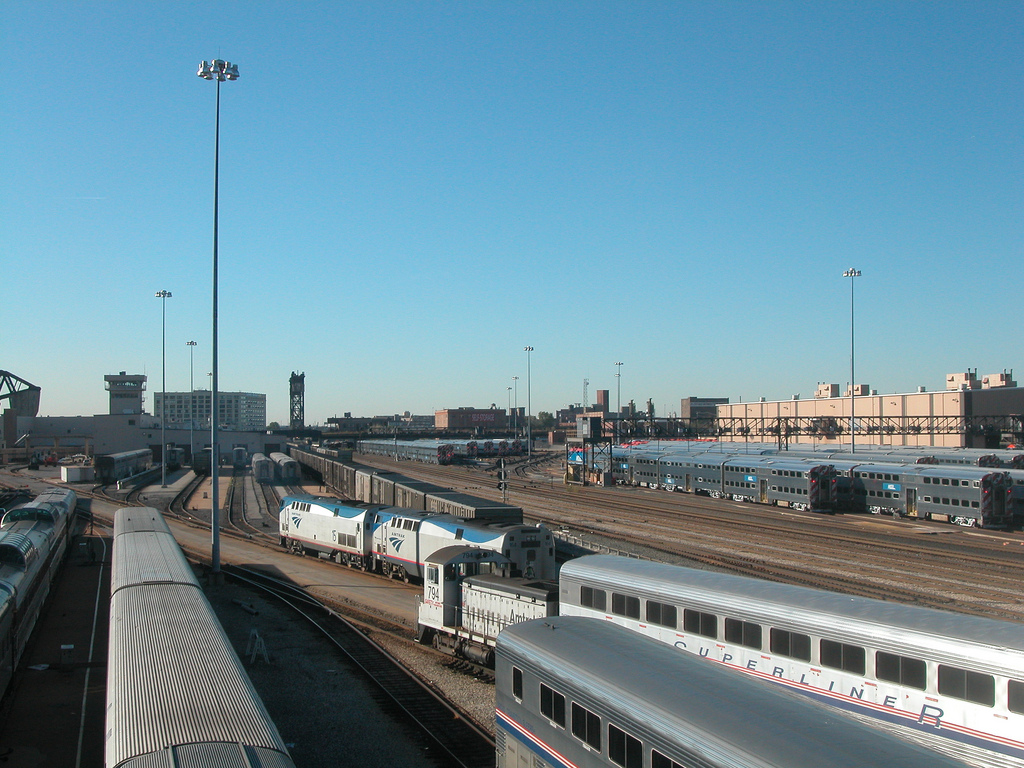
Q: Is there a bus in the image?
A: No, there are no buses.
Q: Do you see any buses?
A: No, there are no buses.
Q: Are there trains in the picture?
A: Yes, there is a train.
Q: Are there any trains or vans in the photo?
A: Yes, there is a train.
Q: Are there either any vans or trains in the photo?
A: Yes, there is a train.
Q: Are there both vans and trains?
A: No, there is a train but no vans.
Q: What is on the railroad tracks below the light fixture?
A: The train is on the tracks.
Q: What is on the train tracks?
A: The train is on the tracks.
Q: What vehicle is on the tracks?
A: The vehicle is a train.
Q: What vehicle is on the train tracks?
A: The vehicle is a train.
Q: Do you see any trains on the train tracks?
A: Yes, there is a train on the train tracks.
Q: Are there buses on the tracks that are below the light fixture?
A: No, there is a train on the tracks.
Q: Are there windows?
A: Yes, there is a window.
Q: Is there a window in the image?
A: Yes, there is a window.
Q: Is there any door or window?
A: Yes, there is a window.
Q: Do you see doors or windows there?
A: Yes, there is a window.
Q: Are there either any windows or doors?
A: Yes, there is a window.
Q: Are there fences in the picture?
A: No, there are no fences.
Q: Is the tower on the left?
A: Yes, the tower is on the left of the image.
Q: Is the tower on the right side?
A: No, the tower is on the left of the image.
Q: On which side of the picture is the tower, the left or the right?
A: The tower is on the left of the image.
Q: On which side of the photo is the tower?
A: The tower is on the left of the image.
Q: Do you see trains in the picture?
A: Yes, there is a train.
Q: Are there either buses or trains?
A: Yes, there is a train.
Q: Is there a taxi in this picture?
A: No, there are no taxis.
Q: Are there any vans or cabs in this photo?
A: No, there are no cabs or vans.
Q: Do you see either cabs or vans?
A: No, there are no cabs or vans.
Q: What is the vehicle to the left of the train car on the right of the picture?
A: The vehicle is a train.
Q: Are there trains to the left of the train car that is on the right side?
A: Yes, there is a train to the left of the train car.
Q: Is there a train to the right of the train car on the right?
A: No, the train is to the left of the train car.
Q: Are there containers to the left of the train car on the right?
A: No, there is a train to the left of the train car.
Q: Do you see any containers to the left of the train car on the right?
A: No, there is a train to the left of the train car.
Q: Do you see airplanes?
A: No, there are no airplanes.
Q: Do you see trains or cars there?
A: Yes, there is a train.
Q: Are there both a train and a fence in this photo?
A: No, there is a train but no fences.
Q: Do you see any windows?
A: Yes, there is a window.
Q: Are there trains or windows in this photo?
A: Yes, there is a window.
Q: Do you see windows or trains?
A: Yes, there is a window.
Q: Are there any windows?
A: Yes, there is a window.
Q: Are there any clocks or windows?
A: Yes, there is a window.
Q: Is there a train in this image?
A: Yes, there is a train.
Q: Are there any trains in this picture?
A: Yes, there is a train.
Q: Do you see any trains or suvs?
A: Yes, there is a train.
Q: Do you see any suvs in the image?
A: No, there are no suvs.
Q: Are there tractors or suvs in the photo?
A: No, there are no suvs or tractors.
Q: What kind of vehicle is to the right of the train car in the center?
A: The vehicle is a train.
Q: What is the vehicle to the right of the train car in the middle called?
A: The vehicle is a train.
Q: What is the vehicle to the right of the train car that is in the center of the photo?
A: The vehicle is a train.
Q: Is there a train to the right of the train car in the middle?
A: Yes, there is a train to the right of the train car.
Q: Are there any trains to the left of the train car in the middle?
A: No, the train is to the right of the train car.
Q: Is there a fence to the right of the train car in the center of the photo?
A: No, there is a train to the right of the train car.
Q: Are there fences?
A: No, there are no fences.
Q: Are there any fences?
A: No, there are no fences.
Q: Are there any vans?
A: No, there are no vans.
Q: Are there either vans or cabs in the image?
A: No, there are no vans or cabs.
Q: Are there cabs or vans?
A: No, there are no vans or cabs.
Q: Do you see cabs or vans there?
A: No, there are no vans or cabs.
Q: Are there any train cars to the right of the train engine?
A: No, the train car is to the left of the train engine.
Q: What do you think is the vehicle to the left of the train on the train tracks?
A: The vehicle is a train car.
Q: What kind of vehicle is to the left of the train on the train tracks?
A: The vehicle is a train car.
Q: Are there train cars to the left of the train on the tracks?
A: Yes, there is a train car to the left of the train.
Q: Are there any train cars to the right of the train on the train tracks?
A: No, the train car is to the left of the train.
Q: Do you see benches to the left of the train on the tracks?
A: No, there is a train car to the left of the train.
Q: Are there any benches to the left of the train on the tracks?
A: No, there is a train car to the left of the train.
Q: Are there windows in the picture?
A: Yes, there is a window.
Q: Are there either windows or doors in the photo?
A: Yes, there is a window.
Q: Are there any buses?
A: No, there are no buses.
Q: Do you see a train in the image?
A: Yes, there is a train.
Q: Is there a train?
A: Yes, there is a train.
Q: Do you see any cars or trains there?
A: Yes, there is a train.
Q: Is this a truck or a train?
A: This is a train.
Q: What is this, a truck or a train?
A: This is a train.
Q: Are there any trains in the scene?
A: Yes, there is a train.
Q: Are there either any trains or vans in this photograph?
A: Yes, there is a train.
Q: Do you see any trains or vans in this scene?
A: Yes, there is a train.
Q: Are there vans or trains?
A: Yes, there is a train.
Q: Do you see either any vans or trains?
A: Yes, there is a train.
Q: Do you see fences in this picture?
A: No, there are no fences.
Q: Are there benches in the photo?
A: No, there are no benches.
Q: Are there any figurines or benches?
A: No, there are no benches or figurines.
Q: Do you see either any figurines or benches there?
A: No, there are no benches or figurines.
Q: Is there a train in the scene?
A: Yes, there is a train.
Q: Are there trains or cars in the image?
A: Yes, there is a train.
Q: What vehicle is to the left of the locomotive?
A: The vehicle is a train.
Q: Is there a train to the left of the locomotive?
A: Yes, there is a train to the left of the locomotive.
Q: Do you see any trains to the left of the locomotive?
A: Yes, there is a train to the left of the locomotive.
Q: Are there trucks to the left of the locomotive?
A: No, there is a train to the left of the locomotive.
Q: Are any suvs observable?
A: No, there are no suvs.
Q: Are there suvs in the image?
A: No, there are no suvs.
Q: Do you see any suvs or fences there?
A: No, there are no suvs or fences.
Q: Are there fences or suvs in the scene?
A: No, there are no suvs or fences.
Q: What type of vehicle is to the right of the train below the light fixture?
A: The vehicle is a locomotive.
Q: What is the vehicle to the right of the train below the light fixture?
A: The vehicle is a locomotive.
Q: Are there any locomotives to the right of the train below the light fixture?
A: Yes, there is a locomotive to the right of the train.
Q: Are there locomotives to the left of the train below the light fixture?
A: No, the locomotive is to the right of the train.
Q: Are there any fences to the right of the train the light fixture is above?
A: No, there is a locomotive to the right of the train.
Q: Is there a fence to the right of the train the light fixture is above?
A: No, there is a locomotive to the right of the train.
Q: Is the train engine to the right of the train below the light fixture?
A: Yes, the train engine is to the right of the train.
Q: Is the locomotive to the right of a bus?
A: No, the locomotive is to the right of the train.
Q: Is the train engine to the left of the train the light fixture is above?
A: No, the train engine is to the right of the train.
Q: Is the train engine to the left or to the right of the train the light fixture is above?
A: The train engine is to the right of the train.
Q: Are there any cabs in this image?
A: No, there are no cabs.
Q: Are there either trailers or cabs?
A: No, there are no cabs or trailers.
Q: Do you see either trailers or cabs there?
A: No, there are no cabs or trailers.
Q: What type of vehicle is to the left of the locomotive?
A: The vehicle is a train car.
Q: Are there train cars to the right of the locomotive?
A: No, the train car is to the left of the locomotive.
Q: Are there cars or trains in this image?
A: Yes, there is a train.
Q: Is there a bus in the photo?
A: No, there are no buses.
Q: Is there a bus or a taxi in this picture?
A: No, there are no buses or taxis.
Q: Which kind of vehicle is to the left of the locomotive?
A: The vehicle is a train.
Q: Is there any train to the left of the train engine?
A: Yes, there is a train to the left of the train engine.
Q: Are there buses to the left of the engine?
A: No, there is a train to the left of the engine.